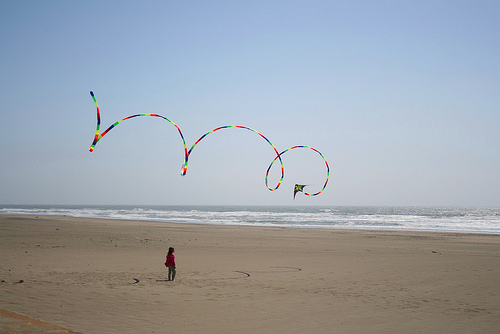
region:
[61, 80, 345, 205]
a ribbon in the sky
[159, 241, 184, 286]
a person standing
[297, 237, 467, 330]
the sand is brown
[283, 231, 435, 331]
the sand on the beach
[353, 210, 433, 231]
the water is white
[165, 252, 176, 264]
a person wearing a red shirt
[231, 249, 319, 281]
a reflection on the sand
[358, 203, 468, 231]
the ocean water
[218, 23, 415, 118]
the sky is clear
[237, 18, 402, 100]
the sky is blue and clear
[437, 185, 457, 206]
part of a cloud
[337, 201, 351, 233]
part of a beach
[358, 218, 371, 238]
part of a wave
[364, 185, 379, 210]
edge of a wave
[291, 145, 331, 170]
part of a rope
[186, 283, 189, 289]
part of a beach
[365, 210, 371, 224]
part of a wall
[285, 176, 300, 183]
edge of a kite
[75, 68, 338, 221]
colorful kite flying in the air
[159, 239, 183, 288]
persn in a red shirt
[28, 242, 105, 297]
footprints on a sandy beach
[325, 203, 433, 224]
white waves cresting on the beach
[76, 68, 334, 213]
ranbow colored kite tail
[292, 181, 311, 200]
black kite flying in the sky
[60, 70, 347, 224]
kite with a very long colorful tail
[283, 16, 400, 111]
clear light blue sky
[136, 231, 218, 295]
solo person standing on the beach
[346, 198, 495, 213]
calm water along the horizon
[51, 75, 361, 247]
a long rainbow tail on kite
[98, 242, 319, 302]
shadow of kite on ground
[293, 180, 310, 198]
a black kite in air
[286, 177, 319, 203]
a black kite with long tail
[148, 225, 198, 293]
a person in red and black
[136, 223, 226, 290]
a person flying a kite on the beach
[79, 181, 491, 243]
white caps of waves coming to shore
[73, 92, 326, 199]
a curvy tail on kite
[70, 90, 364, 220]
only one kite in the air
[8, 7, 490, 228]
a clear blue sky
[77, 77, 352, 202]
a kite with a long tail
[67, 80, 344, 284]
a woman watching a kite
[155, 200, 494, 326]
a woman on the shore of the ocean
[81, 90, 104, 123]
part of the tail of a kite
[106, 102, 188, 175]
part of the tail of a kite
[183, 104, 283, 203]
part of the tail of a kite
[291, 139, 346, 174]
part of the tail of a kite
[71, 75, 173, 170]
part of the tail of a kite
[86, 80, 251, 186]
part of the tail of a kite